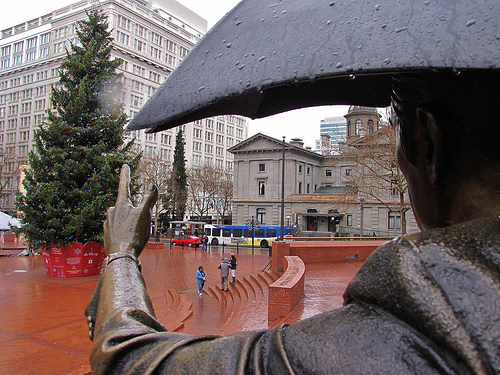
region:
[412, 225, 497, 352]
A statue in the photo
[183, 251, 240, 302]
People walking in the photo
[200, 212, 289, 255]
Blue and white bus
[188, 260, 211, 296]
A woman in the photo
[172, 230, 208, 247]
A red car in the photo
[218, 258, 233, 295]
A man in the photo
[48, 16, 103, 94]
Building in the photo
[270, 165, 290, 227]
A metal pole in the photo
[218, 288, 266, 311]
Stairs outside the building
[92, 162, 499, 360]
bronze statue under umbrella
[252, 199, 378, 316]
red platforms near steps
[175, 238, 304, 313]
orange steps near tree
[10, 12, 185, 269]
tall and green tree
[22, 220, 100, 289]
red base on tree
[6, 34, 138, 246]
many ornaments adorn tree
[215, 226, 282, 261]
blue and white bus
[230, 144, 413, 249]
grey building behind bus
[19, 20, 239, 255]
tall grey building behind tree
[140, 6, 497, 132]
black umbrella over sculpture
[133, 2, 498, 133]
black umbrella of the statue.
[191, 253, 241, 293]
three people on the steps.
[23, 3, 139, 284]
very tall Christmas tree.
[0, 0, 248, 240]
large building in the background.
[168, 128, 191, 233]
Christmas tree in the background.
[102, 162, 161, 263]
hand of bronze statue.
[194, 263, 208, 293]
lady is wearing blue.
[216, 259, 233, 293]
person is wearing gray.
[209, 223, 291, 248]
blue and white bus.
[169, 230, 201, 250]
red car in the distance.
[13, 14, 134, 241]
tall tree in middle of park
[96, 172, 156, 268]
left hand on the statue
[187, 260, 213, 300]
person wearing blue on stairs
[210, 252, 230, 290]
person in hat on stairs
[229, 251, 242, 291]
woman standing on stairs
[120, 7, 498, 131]
black umbrella on the statue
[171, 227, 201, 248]
red car in the background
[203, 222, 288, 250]
blue and white bus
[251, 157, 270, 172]
window on the building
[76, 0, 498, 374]
this is a pewter statue in a courtyard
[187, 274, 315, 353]
a brick staircase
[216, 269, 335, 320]
the ground is wet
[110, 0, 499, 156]
the statue has an umbrella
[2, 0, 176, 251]
this is a large Christmas tree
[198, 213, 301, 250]
a blue and white bus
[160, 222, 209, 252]
this is a red car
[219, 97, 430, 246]
this is a court house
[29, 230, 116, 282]
a large red basket planter that holds the tree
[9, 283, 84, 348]
there is brick in the ground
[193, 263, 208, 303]
woman is standing on the stairs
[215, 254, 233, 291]
woman is standing on the stairs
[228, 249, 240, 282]
woman is standing on the stairs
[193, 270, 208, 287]
woman is wearing a jacket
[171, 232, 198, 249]
car color is red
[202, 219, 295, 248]
bus is blue and white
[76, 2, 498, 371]
statue is brown and black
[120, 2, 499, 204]
statue is holding a umbrella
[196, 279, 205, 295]
woman is wearing pants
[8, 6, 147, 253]
A large Christmas tree with lights.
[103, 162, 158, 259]
A bronze hand with pointing finger.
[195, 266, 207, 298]
Woman in mostly blue.